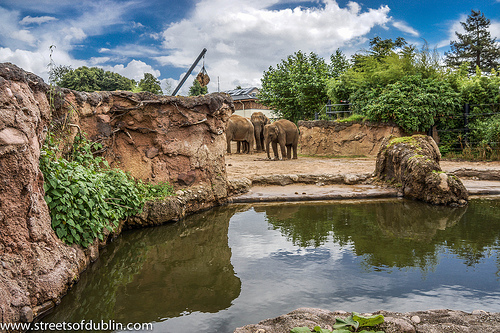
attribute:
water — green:
[26, 198, 497, 331]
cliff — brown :
[4, 75, 227, 313]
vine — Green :
[45, 132, 181, 249]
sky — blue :
[3, 2, 497, 94]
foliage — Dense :
[258, 56, 494, 141]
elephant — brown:
[266, 122, 302, 157]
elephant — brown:
[223, 116, 256, 151]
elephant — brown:
[248, 111, 266, 148]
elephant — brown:
[264, 121, 298, 154]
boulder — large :
[374, 130, 469, 209]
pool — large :
[35, 196, 489, 330]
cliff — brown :
[0, 70, 237, 330]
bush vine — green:
[36, 147, 116, 243]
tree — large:
[267, 55, 332, 117]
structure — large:
[218, 79, 295, 129]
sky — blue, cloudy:
[78, 9, 420, 93]